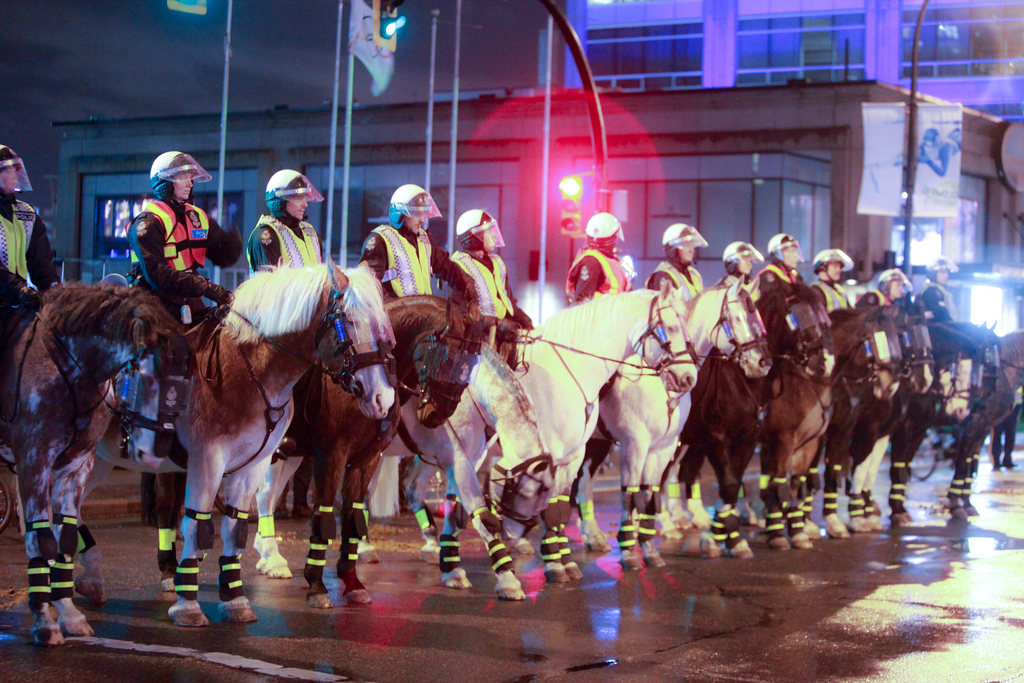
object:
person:
[716, 236, 761, 303]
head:
[653, 220, 717, 268]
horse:
[743, 280, 847, 556]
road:
[248, 588, 968, 670]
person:
[452, 196, 531, 339]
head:
[584, 208, 636, 251]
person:
[247, 165, 334, 296]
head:
[251, 163, 334, 226]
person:
[559, 209, 640, 307]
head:
[384, 179, 449, 242]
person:
[649, 220, 714, 325]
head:
[454, 200, 515, 257]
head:
[715, 229, 766, 286]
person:
[755, 228, 811, 293]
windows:
[567, 16, 711, 92]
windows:
[889, 2, 1024, 86]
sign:
[845, 100, 993, 224]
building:
[52, 75, 1016, 483]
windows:
[723, 10, 888, 93]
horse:
[829, 290, 909, 539]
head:
[848, 291, 906, 410]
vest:
[128, 198, 213, 275]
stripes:
[387, 227, 418, 297]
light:
[551, 166, 594, 202]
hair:
[217, 258, 395, 345]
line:
[69, 636, 352, 683]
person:
[113, 138, 248, 291]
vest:
[240, 217, 336, 276]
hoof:
[162, 595, 216, 636]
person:
[0, 134, 63, 309]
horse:
[0, 272, 200, 656]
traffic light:
[365, 0, 422, 60]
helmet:
[140, 145, 216, 181]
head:
[150, 147, 206, 208]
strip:
[19, 581, 55, 602]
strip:
[46, 577, 86, 596]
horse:
[160, 258, 408, 641]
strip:
[50, 508, 82, 532]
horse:
[376, 266, 503, 658]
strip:
[25, 516, 53, 534]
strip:
[175, 562, 203, 578]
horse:
[504, 274, 704, 632]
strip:
[173, 580, 201, 595]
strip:
[307, 539, 333, 554]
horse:
[684, 266, 793, 571]